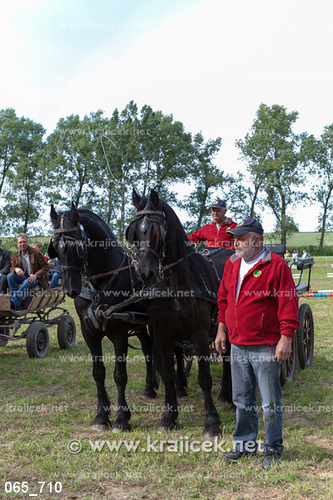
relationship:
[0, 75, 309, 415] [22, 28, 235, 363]
people at park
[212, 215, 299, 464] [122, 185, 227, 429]
man standing next to horse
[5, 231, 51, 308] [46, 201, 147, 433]
man watching horse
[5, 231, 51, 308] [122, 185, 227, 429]
man watching horse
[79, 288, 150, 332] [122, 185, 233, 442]
hardware on horse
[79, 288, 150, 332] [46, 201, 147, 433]
hardware on horse